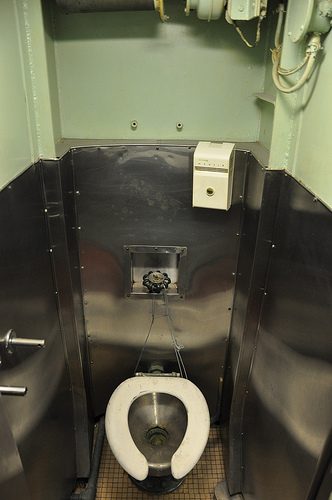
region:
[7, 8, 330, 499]
an old bathroom with metal wall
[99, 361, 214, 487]
a toilet of a bathroom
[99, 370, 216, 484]
sit of toilet is plastic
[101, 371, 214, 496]
toilet is metal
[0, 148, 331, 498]
half wall of bathroom is metal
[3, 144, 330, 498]
wall is color silver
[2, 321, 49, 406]
two rods on left side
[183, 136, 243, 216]
a white box above the toilet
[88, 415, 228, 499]
floor of bathroom is yellow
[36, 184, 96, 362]
knobs on wall of bathroom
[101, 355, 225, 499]
a metal toilet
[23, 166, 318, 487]
a bathroom stall in a public restroom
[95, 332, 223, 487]
a public toilet in a restroom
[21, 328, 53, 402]
an empty toiler paper holder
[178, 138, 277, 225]
an air freshener in a public restroom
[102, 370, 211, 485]
a toilet with no water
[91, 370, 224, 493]
an empty toilet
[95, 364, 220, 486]
a metal toilet with a white toilet seat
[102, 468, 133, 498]
a yellow tiled floor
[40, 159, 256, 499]
a bathroom stall with metal walls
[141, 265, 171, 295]
valve for the toilet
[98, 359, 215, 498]
stainless steel toilet bowl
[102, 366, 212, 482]
worn white toilet seat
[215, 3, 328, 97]
electrical wires hanging down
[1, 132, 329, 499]
stainless steel walls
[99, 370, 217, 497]
rusty old toilet bowl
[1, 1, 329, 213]
green painted upper walls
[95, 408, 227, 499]
dirty brown tile floor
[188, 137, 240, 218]
white dispenser on the wall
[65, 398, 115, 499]
pipe running along the floor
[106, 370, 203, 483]
steel toilet in bathroom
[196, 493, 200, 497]
small square tile on floor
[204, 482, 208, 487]
small square tile on floor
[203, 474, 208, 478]
small square tile on floor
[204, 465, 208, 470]
small square tile on floor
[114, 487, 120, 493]
small square tile on floor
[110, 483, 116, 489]
small square tile on floor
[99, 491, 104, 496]
small square tile on floor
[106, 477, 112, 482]
small square tile on floor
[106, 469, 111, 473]
small square tile on floor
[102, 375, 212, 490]
White toilet seat covering stainless steel bowl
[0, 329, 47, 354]
Stainless steel toilet flush apparatus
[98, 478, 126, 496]
Small-sized ceramic tiles underneath toilet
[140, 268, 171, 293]
Black metal water valve over toilet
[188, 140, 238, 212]
White sensor box attached to wall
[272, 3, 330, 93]
Plumbing pipes and equipment for toilet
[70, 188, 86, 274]
Rivets attaching stainless steel sheets to wall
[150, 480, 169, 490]
Metal base of toilet attached to tiled floor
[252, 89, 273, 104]
Narrow green-painted ledge on wall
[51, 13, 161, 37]
Rectangular shadow of tubular plumbing apparatus